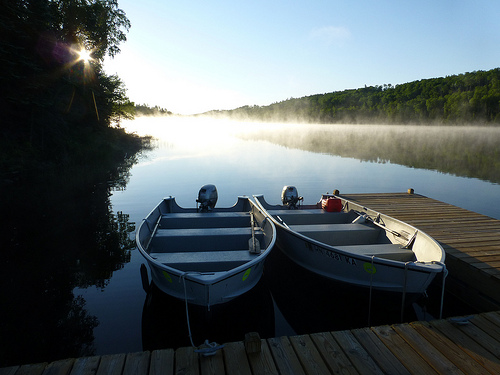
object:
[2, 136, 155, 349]
trees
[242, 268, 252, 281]
circles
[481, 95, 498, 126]
tree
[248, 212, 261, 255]
oar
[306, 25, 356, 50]
clouds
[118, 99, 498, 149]
steam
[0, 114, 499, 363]
lake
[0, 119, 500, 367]
water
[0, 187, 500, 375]
dock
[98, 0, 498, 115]
sky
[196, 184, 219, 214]
motor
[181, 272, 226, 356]
ropes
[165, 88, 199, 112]
clouds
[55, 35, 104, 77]
sunlight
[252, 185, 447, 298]
boat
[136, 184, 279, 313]
boat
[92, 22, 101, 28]
leaves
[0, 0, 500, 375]
scene